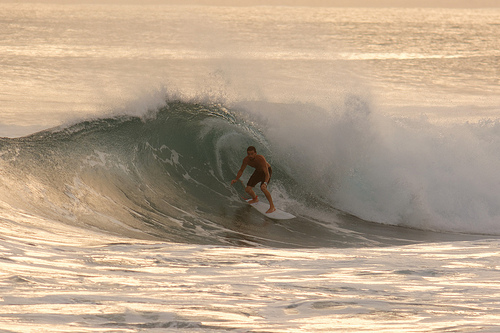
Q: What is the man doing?
A: Surfing.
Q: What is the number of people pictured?
A: 1.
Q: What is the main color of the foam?
A: White.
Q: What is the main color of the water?
A: Gray.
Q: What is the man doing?
A: Riding the wave.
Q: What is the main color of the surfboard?
A: White.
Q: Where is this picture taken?
A: Beach.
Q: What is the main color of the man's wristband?
A: White.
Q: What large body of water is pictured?
A: Ocean.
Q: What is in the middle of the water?
A: Large wave.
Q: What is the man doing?
A: Surfing.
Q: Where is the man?
A: Eye of waves.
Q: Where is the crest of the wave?
A: Above man.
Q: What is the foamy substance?
A: Salt pools.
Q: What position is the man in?
A: Shallow squat.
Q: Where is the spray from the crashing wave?
A: Right.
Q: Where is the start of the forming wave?
A: Left.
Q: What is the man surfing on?
A: A wave.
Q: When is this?
A: Daytime.